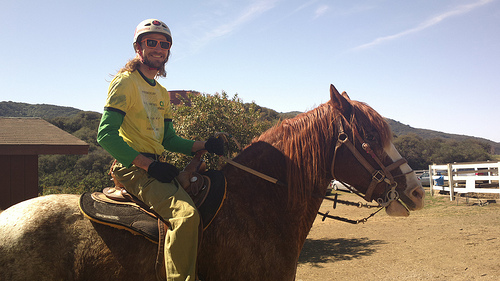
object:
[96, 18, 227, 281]
man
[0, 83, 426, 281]
horse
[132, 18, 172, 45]
helmet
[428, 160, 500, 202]
fence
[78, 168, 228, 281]
blanket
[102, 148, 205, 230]
saddle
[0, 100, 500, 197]
mountains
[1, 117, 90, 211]
building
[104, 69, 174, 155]
shirt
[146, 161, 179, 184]
gloves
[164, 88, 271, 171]
bush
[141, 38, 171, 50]
glasses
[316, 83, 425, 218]
head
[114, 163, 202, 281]
legs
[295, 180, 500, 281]
ground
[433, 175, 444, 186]
bin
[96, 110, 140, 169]
sleeves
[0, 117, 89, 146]
roof